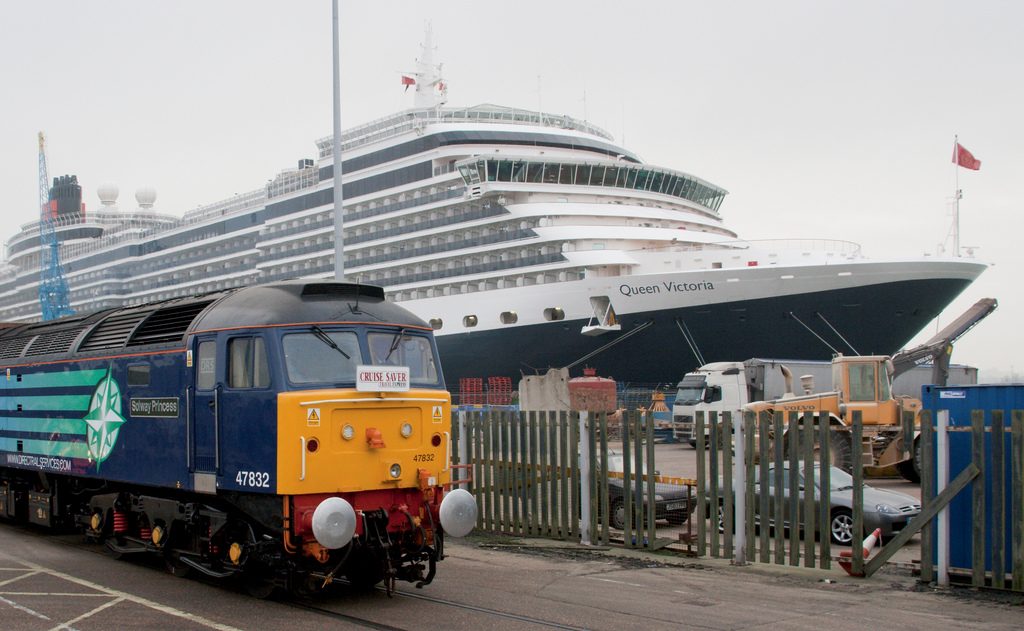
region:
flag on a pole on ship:
[937, 124, 1000, 267]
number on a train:
[217, 460, 289, 499]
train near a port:
[9, 267, 494, 618]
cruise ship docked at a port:
[4, 94, 1004, 388]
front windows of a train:
[270, 315, 453, 402]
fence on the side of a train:
[455, 389, 941, 596]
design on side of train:
[83, 368, 138, 483]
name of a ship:
[606, 265, 727, 308]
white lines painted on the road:
[4, 553, 185, 626]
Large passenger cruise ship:
[2, 10, 983, 372]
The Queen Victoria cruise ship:
[0, 18, 997, 383]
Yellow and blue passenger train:
[0, 277, 513, 611]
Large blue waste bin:
[912, 376, 1020, 576]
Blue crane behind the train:
[21, 130, 75, 328]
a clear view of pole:
[287, 21, 377, 217]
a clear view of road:
[533, 559, 696, 629]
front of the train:
[307, 476, 555, 606]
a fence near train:
[563, 382, 816, 541]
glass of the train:
[265, 297, 528, 424]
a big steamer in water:
[151, 56, 914, 468]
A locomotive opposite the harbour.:
[0, 278, 462, 596]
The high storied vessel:
[0, 24, 984, 380]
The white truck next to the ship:
[670, 358, 836, 435]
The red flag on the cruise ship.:
[954, 134, 983, 270]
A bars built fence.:
[455, 406, 1021, 593]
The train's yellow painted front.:
[270, 387, 458, 493]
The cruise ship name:
[616, 278, 718, 298]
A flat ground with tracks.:
[0, 534, 1019, 629]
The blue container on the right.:
[931, 378, 1023, 579]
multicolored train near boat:
[16, 240, 468, 582]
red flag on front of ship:
[896, 100, 989, 250]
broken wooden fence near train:
[428, 369, 994, 581]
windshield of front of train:
[266, 288, 448, 421]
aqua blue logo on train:
[16, 358, 146, 491]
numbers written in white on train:
[228, 433, 279, 492]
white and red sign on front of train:
[343, 350, 426, 399]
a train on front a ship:
[0, 180, 563, 622]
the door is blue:
[177, 321, 233, 484]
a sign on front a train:
[345, 350, 417, 410]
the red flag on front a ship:
[942, 112, 988, 268]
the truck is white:
[661, 344, 787, 455]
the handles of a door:
[173, 375, 229, 478]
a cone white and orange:
[837, 518, 891, 578]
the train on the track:
[2, 281, 591, 627]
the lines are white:
[2, 547, 241, 628]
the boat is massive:
[0, 0, 996, 423]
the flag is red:
[953, 141, 983, 173]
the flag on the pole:
[953, 127, 980, 248]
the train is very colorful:
[2, 278, 480, 608]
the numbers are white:
[236, 465, 274, 488]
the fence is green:
[442, 407, 1022, 598]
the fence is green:
[452, 402, 1022, 599]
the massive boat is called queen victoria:
[0, 0, 994, 412]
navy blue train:
[1, 250, 479, 623]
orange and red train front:
[251, 312, 518, 616]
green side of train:
[1, 363, 157, 512]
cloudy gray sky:
[2, 7, 1017, 387]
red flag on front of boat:
[930, 121, 994, 201]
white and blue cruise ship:
[14, 37, 998, 401]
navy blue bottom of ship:
[431, 278, 982, 434]